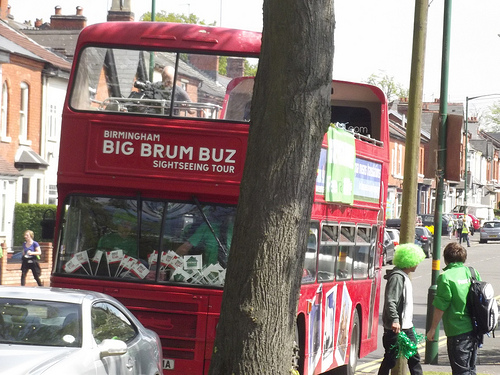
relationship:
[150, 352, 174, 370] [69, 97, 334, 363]
license plate on bus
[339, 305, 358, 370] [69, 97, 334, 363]
wheel on bus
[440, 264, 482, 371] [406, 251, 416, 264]
person wearing a wig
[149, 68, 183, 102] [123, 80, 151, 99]
man has a camera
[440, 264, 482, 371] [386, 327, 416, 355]
person carrying pom poms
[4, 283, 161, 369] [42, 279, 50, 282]
car on road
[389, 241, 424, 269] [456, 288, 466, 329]
wig matches jacket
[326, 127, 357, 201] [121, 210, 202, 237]
banner behind windshield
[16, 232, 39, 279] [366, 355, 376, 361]
pedestrian walking down street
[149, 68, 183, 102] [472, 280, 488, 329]
man wearing a backpack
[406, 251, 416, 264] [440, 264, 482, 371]
wig on person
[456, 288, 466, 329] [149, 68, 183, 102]
jacket on man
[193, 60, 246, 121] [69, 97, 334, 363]
window attached to bus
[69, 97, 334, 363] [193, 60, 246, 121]
bus has window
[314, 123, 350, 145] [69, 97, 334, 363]
towel hanging over bus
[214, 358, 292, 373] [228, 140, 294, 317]
stem of tree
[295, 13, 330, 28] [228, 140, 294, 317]
bark on tree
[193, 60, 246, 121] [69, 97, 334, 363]
window on bus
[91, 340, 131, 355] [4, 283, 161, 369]
mirror on car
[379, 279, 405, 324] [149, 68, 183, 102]
arm of man